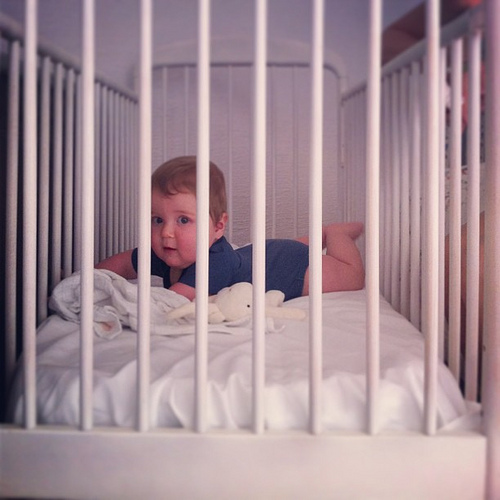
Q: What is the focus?
A: Baby in crib.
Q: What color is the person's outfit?
A: Blue.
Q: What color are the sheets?
A: White.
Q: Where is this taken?
A: Crib.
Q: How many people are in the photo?
A: 1.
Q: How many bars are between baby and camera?
A: 8.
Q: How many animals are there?
A: 0.